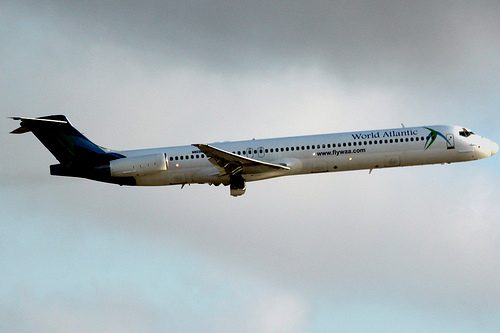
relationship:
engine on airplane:
[109, 148, 176, 184] [11, 87, 482, 198]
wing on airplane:
[180, 137, 283, 188] [12, 97, 482, 192]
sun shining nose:
[439, 91, 468, 145] [454, 124, 483, 158]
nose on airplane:
[454, 124, 483, 158] [10, 92, 484, 209]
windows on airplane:
[294, 138, 423, 150] [11, 87, 482, 198]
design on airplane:
[424, 125, 445, 146] [20, 103, 478, 203]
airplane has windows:
[5, 114, 499, 199] [322, 136, 428, 149]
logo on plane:
[428, 125, 450, 150] [10, 108, 495, 200]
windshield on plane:
[458, 129, 474, 136] [10, 108, 495, 200]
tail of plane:
[6, 109, 132, 192] [10, 108, 495, 200]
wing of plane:
[180, 137, 283, 188] [10, 108, 495, 200]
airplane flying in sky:
[7, 113, 497, 199] [3, 1, 496, 331]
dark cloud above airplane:
[48, 2, 498, 86] [7, 113, 497, 199]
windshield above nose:
[458, 129, 474, 136] [474, 138, 497, 158]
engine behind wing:
[109, 152, 168, 178] [190, 143, 288, 179]